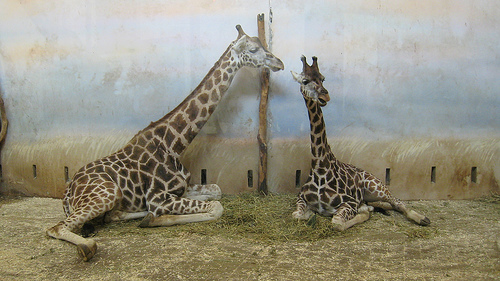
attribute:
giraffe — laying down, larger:
[25, 26, 282, 266]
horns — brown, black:
[234, 23, 247, 36]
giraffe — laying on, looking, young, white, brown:
[287, 47, 437, 233]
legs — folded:
[44, 170, 226, 263]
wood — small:
[257, 11, 284, 205]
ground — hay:
[54, 242, 479, 279]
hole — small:
[23, 158, 44, 190]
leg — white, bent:
[138, 196, 223, 230]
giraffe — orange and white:
[31, 6, 452, 278]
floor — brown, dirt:
[0, 195, 499, 279]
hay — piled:
[211, 181, 339, 248]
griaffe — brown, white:
[288, 52, 435, 230]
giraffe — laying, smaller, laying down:
[294, 56, 430, 241]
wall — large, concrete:
[18, 22, 140, 114]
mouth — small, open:
[315, 93, 332, 105]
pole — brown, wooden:
[251, 8, 277, 192]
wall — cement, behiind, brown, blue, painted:
[2, 2, 498, 196]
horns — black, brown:
[296, 52, 321, 68]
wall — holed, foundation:
[371, 44, 463, 124]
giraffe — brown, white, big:
[46, 23, 286, 258]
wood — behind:
[253, 91, 270, 181]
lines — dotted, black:
[30, 160, 479, 185]